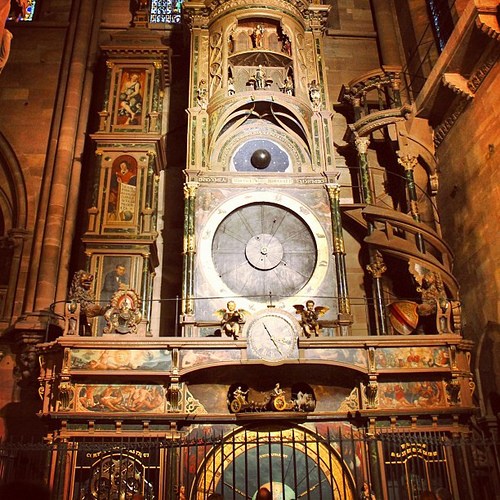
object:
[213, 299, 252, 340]
statue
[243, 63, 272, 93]
statue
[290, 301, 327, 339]
angel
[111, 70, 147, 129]
painting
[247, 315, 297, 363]
clock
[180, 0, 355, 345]
tower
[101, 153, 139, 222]
painting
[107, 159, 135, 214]
man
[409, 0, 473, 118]
balcony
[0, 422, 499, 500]
gate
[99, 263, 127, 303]
man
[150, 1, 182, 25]
window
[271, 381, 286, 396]
people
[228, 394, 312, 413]
chariots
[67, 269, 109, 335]
lion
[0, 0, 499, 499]
picture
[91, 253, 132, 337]
painting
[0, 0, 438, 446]
wall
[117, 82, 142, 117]
dress